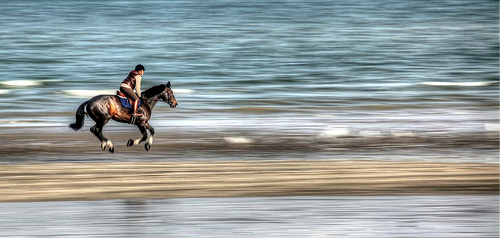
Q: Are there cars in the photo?
A: No, there are no cars.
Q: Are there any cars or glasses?
A: No, there are no cars or glasses.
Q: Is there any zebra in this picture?
A: No, there are no zebras.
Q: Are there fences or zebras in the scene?
A: No, there are no zebras or fences.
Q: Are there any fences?
A: No, there are no fences.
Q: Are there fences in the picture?
A: No, there are no fences.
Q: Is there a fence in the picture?
A: No, there are no fences.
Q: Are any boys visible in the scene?
A: No, there are no boys.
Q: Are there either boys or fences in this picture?
A: No, there are no boys or fences.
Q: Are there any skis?
A: No, there are no skis.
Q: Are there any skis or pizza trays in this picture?
A: No, there are no skis or pizza trays.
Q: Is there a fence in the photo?
A: No, there are no fences.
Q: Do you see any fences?
A: No, there are no fences.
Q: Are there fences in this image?
A: No, there are no fences.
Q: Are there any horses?
A: Yes, there is a horse.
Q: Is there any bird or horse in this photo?
A: Yes, there is a horse.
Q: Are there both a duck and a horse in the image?
A: No, there is a horse but no ducks.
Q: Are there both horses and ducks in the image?
A: No, there is a horse but no ducks.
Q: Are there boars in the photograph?
A: No, there are no boars.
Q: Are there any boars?
A: No, there are no boars.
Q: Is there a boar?
A: No, there are no boars.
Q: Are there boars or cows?
A: No, there are no boars or cows.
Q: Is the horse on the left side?
A: Yes, the horse is on the left of the image.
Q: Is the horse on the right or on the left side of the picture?
A: The horse is on the left of the image.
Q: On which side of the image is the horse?
A: The horse is on the left of the image.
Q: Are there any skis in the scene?
A: No, there are no skis.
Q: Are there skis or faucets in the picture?
A: No, there are no skis or faucets.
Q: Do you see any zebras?
A: No, there are no zebras.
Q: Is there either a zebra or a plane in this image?
A: No, there are no zebras or airplanes.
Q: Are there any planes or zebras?
A: No, there are no zebras or planes.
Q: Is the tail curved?
A: Yes, the tail is curved.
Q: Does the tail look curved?
A: Yes, the tail is curved.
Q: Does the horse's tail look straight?
A: No, the tail is curved.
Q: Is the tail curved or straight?
A: The tail is curved.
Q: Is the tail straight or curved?
A: The tail is curved.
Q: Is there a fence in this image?
A: No, there are no fences.